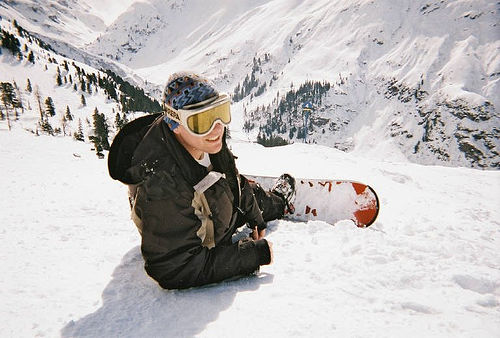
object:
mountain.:
[0, 0, 500, 70]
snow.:
[0, 165, 105, 336]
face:
[180, 99, 233, 155]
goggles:
[161, 93, 235, 135]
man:
[105, 73, 294, 291]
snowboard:
[294, 176, 380, 230]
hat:
[157, 71, 223, 130]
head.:
[160, 71, 234, 158]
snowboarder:
[102, 71, 380, 293]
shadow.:
[48, 245, 272, 337]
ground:
[0, 138, 103, 338]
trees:
[0, 15, 107, 148]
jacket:
[105, 114, 278, 294]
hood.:
[104, 105, 155, 191]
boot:
[271, 170, 300, 220]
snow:
[378, 0, 500, 338]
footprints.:
[380, 167, 500, 267]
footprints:
[275, 229, 500, 338]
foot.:
[268, 173, 298, 218]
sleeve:
[126, 171, 273, 292]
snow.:
[260, 180, 372, 229]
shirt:
[194, 152, 223, 168]